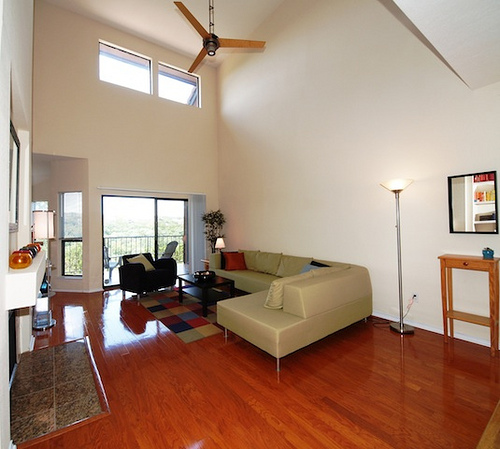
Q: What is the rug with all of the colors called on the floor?
A: Area rug.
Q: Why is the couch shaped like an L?
A: It is a sectional.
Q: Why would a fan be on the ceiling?
A: Too cool off area.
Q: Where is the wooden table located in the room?
A: Under mirror.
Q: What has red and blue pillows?
A: Sofa.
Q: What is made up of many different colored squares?
A: Rug.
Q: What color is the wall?
A: White.